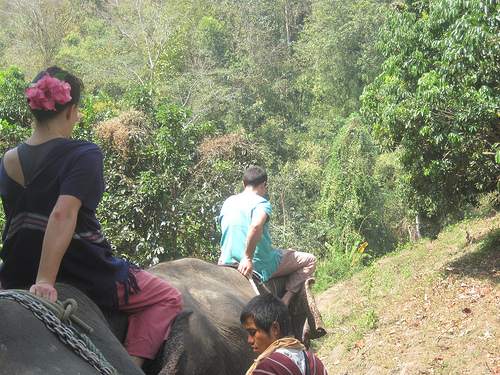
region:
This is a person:
[204, 157, 334, 286]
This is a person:
[0, 52, 192, 372]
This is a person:
[225, 289, 327, 372]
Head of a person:
[232, 155, 270, 200]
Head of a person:
[238, 292, 291, 366]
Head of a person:
[16, 58, 81, 150]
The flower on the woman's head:
[22, 75, 67, 110]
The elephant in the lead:
[145, 255, 320, 371]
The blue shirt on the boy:
[211, 190, 276, 280]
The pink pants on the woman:
[110, 265, 180, 355]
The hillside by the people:
[312, 210, 493, 370]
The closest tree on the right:
[360, 0, 495, 190]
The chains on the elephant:
[0, 290, 115, 370]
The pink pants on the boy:
[267, 250, 314, 290]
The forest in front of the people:
[0, 1, 426, 296]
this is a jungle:
[47, 64, 458, 372]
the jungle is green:
[165, 20, 330, 184]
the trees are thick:
[210, 73, 372, 208]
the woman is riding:
[42, 84, 137, 358]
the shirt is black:
[7, 127, 127, 265]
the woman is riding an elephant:
[52, 263, 169, 374]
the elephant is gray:
[47, 297, 137, 365]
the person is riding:
[200, 177, 301, 267]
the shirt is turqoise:
[222, 184, 319, 308]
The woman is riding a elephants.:
[1, 63, 185, 355]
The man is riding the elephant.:
[198, 157, 320, 299]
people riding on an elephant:
[2, 32, 346, 366]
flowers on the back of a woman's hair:
[17, 60, 75, 129]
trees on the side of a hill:
[12, 10, 474, 255]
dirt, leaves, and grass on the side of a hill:
[337, 219, 497, 373]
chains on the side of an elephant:
[2, 272, 126, 370]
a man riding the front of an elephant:
[200, 161, 338, 341]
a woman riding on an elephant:
[2, 50, 203, 359]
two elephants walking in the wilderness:
[2, 228, 344, 374]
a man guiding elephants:
[221, 281, 331, 373]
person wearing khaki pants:
[201, 164, 334, 309]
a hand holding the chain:
[24, 276, 59, 320]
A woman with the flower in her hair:
[22, 61, 84, 140]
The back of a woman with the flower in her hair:
[7, 61, 106, 236]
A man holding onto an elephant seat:
[216, 161, 286, 283]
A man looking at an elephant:
[228, 291, 299, 369]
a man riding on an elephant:
[149, 161, 329, 308]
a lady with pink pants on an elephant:
[5, 57, 190, 362]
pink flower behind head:
[24, 78, 74, 112]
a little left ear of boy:
[269, 317, 282, 334]